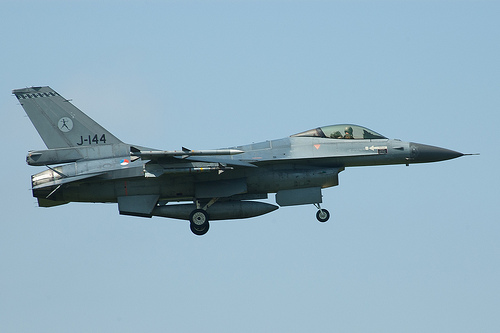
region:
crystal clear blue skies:
[176, 72, 263, 89]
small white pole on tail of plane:
[60, 95, 80, 105]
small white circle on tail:
[52, 112, 77, 132]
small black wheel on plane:
[311, 200, 333, 220]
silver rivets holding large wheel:
[183, 192, 224, 210]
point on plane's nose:
[446, 143, 486, 158]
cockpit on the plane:
[283, 102, 394, 144]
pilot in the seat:
[332, 115, 363, 141]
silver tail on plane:
[10, 80, 136, 175]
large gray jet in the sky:
[16, 70, 488, 214]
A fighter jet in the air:
[15, 76, 487, 235]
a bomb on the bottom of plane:
[152, 196, 279, 227]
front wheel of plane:
[316, 201, 332, 221]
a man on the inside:
[338, 124, 363, 139]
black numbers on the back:
[67, 127, 124, 153]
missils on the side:
[125, 145, 255, 164]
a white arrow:
[362, 143, 387, 154]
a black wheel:
[189, 209, 209, 229]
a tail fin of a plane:
[14, 79, 118, 149]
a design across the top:
[9, 80, 64, 108]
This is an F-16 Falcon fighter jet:
[7, 74, 491, 249]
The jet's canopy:
[294, 120, 391, 141]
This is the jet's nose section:
[389, 130, 485, 176]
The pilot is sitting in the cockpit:
[331, 125, 375, 140]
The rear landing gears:
[181, 201, 219, 236]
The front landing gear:
[309, 198, 334, 225]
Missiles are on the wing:
[128, 142, 247, 179]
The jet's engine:
[26, 165, 67, 208]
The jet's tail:
[8, 80, 130, 164]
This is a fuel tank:
[117, 194, 282, 222]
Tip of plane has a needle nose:
[464, 150, 482, 157]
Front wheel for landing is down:
[312, 206, 331, 223]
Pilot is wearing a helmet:
[342, 124, 352, 135]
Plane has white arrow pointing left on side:
[369, 144, 389, 151]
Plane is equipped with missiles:
[136, 147, 243, 157]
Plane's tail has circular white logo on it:
[55, 115, 75, 133]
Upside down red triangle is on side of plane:
[312, 140, 323, 151]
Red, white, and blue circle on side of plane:
[117, 157, 129, 168]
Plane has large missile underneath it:
[157, 199, 279, 218]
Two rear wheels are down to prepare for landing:
[185, 211, 211, 236]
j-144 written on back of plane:
[70, 126, 112, 151]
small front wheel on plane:
[312, 203, 348, 233]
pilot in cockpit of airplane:
[335, 114, 358, 143]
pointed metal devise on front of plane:
[455, 148, 479, 169]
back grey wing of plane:
[15, 84, 100, 151]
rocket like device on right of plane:
[150, 134, 247, 177]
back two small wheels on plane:
[177, 201, 214, 245]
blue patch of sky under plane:
[366, 253, 413, 330]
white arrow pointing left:
[368, 144, 400, 161]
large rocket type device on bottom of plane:
[156, 201, 268, 224]